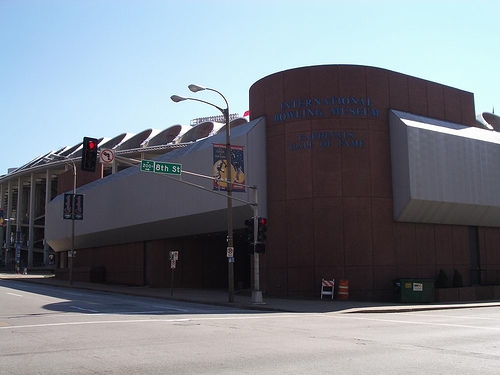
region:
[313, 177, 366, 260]
aprt of a line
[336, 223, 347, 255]
aprt of a line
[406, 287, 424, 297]
the trash bin is green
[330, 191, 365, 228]
the building is brown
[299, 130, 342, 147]
the words are blue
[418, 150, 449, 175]
the building is gray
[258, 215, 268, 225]
the light is red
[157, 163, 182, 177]
the sign is on the pole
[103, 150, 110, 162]
the arrow is black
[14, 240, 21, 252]
the sign is blue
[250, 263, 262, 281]
the pole is gray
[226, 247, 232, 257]
the sign is white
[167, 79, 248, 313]
street lights on a metal pole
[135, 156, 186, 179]
green street sign on metal pole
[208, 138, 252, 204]
multicolored banner on the side of a building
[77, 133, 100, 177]
black traffic light showing red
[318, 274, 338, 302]
safety barricade standing against a wall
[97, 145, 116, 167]
white street sign on a metal pole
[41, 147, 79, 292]
street light on a metal pole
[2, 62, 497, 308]
large building next to the road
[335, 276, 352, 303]
large orange safety cone next to building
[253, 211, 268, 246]
black traffic light showing red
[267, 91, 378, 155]
Blue words written on the corner of building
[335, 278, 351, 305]
orange and white barrel blockade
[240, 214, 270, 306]
traffic signal on corner of street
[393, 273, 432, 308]
green dumpster on the sidewalk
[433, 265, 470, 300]
two bushes in a concrete planter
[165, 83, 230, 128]
a pole with two street lights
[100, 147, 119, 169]
a no left turn signal hanging above the street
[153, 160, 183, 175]
a green and white street sign that says 8th St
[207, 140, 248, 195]
a street sign advertisement on a light pole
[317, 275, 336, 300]
a striped orange and white barrier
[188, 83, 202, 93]
the light is off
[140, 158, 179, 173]
a street name sign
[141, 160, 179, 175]
green and white sign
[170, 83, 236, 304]
a couple of street lights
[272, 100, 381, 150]
blue writing on wall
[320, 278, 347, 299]
some construction equipment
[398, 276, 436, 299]
the dumpster is green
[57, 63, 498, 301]
building is brown and gray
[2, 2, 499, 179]
no clouds in the sky